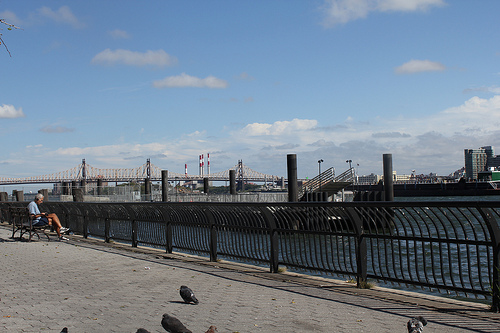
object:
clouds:
[156, 53, 218, 93]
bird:
[177, 285, 197, 302]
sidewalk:
[44, 259, 72, 289]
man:
[24, 191, 68, 241]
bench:
[9, 197, 59, 240]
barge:
[0, 181, 499, 312]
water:
[416, 190, 488, 218]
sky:
[207, 41, 241, 73]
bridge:
[0, 157, 356, 191]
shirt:
[25, 201, 41, 215]